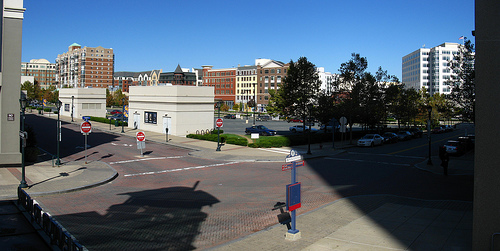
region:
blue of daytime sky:
[23, 1, 473, 76]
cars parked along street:
[358, 123, 436, 148]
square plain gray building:
[128, 85, 215, 137]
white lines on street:
[114, 154, 229, 176]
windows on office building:
[401, 46, 466, 94]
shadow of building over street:
[291, 125, 478, 247]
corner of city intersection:
[1, 157, 117, 200]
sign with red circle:
[81, 119, 93, 161]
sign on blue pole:
[283, 150, 301, 232]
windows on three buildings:
[204, 68, 284, 104]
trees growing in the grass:
[264, 32, 391, 155]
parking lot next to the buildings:
[221, 100, 294, 140]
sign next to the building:
[71, 117, 102, 174]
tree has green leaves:
[280, 56, 340, 132]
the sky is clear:
[141, 1, 265, 50]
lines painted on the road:
[111, 137, 241, 192]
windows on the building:
[412, 53, 467, 99]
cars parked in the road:
[365, 105, 430, 165]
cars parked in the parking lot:
[207, 96, 315, 153]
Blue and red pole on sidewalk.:
[273, 173, 313, 248]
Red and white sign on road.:
[131, 128, 146, 163]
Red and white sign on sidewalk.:
[76, 119, 116, 189]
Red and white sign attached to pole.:
[198, 113, 243, 153]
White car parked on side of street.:
[358, 130, 377, 140]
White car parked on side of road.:
[444, 136, 455, 155]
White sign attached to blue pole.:
[273, 145, 314, 164]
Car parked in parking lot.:
[249, 120, 289, 146]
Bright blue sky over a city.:
[0, 0, 486, 121]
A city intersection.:
[0, 0, 340, 245]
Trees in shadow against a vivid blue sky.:
[270, 30, 395, 145]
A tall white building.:
[395, 26, 475, 126]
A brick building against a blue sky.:
[41, 20, 116, 85]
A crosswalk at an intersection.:
[95, 126, 261, 181]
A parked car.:
[243, 121, 278, 141]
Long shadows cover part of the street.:
[206, 2, 496, 248]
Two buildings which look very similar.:
[53, 70, 220, 146]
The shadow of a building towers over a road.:
[39, 164, 250, 247]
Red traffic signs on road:
[77, 118, 227, 143]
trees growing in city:
[278, 41, 475, 129]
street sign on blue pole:
[282, 146, 304, 233]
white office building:
[125, 83, 215, 135]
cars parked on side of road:
[351, 120, 473, 150]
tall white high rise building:
[399, 42, 474, 98]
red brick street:
[52, 145, 445, 248]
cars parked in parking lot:
[242, 123, 316, 135]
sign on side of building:
[7, 113, 15, 122]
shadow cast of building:
[41, 180, 226, 249]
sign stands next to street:
[275, 142, 304, 242]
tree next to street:
[271, 50, 321, 156]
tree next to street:
[319, 46, 385, 137]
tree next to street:
[385, 77, 422, 139]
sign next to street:
[132, 127, 148, 163]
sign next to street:
[77, 117, 92, 166]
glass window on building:
[441, 48, 448, 56]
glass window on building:
[439, 56, 451, 59]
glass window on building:
[441, 86, 450, 91]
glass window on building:
[421, 50, 429, 55]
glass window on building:
[422, 63, 429, 68]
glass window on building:
[422, 79, 432, 85]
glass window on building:
[262, 74, 274, 84]